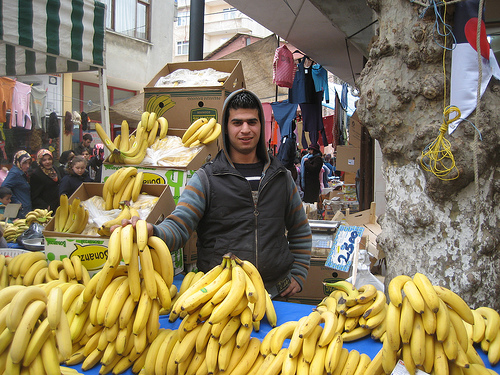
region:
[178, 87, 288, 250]
this is a man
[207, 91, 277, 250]
the man is staring at the camera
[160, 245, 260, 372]
these are bunches of banana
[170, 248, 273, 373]
the banana are ripe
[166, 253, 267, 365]
the banana are ripe in color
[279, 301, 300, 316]
this is the table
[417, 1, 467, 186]
yellow cord hanging over bananas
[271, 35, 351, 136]
clothes hanging from canopy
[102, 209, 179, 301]
hand holding bunch of bananas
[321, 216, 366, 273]
blue and white price tag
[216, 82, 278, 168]
brown hoodie over head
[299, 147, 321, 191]
blue scarf around neck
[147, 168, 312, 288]
stripes on sleeves of jacket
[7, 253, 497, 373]
bananas for sale on table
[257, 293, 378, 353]
blue cover on table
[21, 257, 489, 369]
large bunches of bananas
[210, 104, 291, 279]
man in gray hoodie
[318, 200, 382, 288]
price on the sign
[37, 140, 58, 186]
woman with scarf on head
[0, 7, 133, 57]
green and white awning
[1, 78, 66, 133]
clothes hung up on line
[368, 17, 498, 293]
large rock on side of person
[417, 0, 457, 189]
yellow and blue string hanging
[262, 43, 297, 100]
pink sweater hanging on line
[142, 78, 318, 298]
a man buying bananas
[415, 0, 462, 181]
a yellow rope hanging down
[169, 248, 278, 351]
a banana bunch on the table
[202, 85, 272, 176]
the man is wearing a hood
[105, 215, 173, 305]
his hand is holding a banana bunch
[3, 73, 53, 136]
clothes hanging from a line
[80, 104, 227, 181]
bananas in a box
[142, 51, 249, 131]
a banana box on top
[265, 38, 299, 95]
a shirt hanging from the ceiling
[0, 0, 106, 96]
a canopy over the walkway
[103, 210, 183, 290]
Man holding yellow bananas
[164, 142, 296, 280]
man wearing a gray shirt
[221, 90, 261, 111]
man with black hair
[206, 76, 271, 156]
man with a hood on its head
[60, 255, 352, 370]
bananas on display to be sold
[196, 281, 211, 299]
green sticker on a banana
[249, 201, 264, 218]
zipper on a gray jacket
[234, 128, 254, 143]
man with a smile on his face